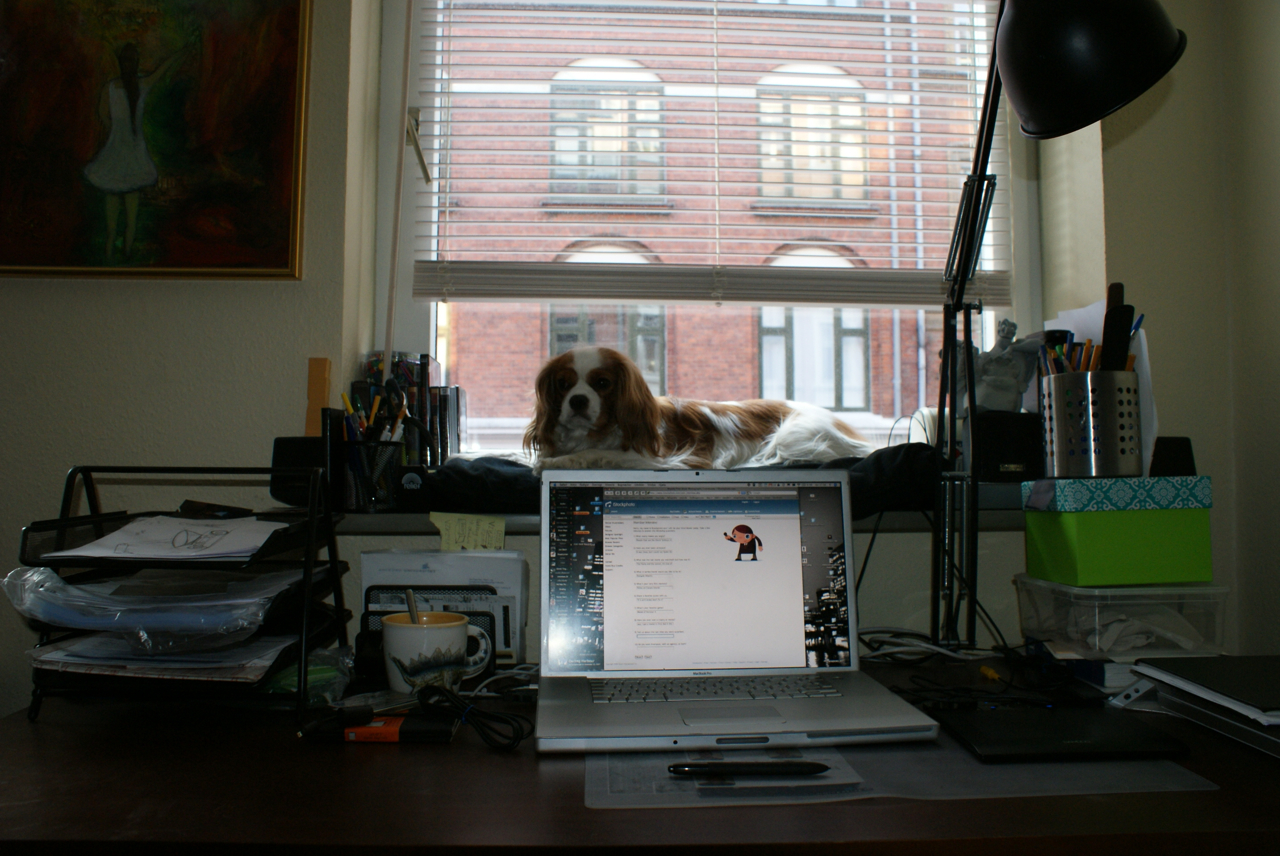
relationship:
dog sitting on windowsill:
[475, 336, 844, 482] [403, 434, 1075, 508]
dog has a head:
[522, 342, 871, 470] [533, 348, 639, 433]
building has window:
[440, 2, 981, 453] [756, 240, 876, 411]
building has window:
[440, 2, 981, 453] [542, 55, 671, 193]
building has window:
[440, 2, 981, 453] [756, 65, 864, 209]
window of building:
[756, 240, 876, 411] [440, 2, 981, 453]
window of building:
[756, 65, 864, 209] [440, 2, 981, 453]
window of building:
[547, 55, 663, 193] [440, 2, 981, 453]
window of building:
[756, 240, 876, 411] [424, 30, 1012, 504]